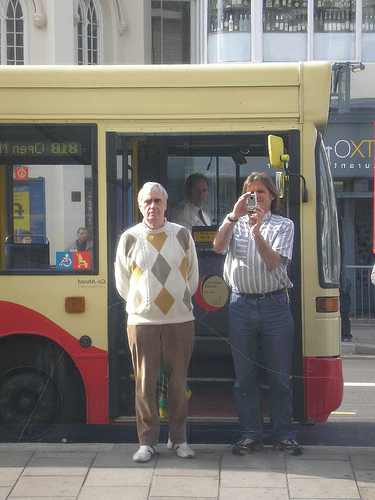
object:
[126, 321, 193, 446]
pants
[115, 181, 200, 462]
man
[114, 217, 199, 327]
sweater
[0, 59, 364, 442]
bus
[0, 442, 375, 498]
sidewalk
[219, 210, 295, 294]
shirt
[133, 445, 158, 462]
shoe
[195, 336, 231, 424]
stair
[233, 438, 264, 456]
man's shoes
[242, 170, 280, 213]
hair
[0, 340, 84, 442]
tire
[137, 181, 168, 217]
white hair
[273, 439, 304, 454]
shoes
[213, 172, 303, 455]
man